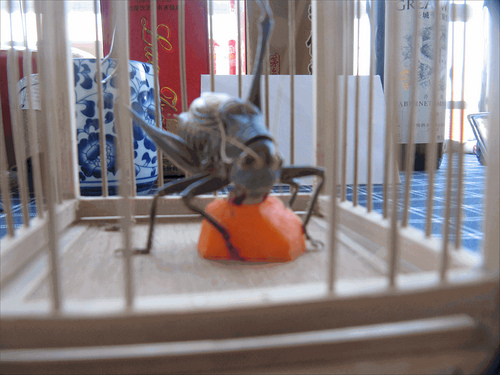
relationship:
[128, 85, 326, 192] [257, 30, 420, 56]
insect eating in cage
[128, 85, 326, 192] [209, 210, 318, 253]
insect eating carrot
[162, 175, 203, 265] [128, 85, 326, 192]
legs of insect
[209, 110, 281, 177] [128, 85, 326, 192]
antenna of insect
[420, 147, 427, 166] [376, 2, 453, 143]
wine bottle with white label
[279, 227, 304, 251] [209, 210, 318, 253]
edge of carrot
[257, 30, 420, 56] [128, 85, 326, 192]
cage holding insect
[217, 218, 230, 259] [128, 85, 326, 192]
hand of insect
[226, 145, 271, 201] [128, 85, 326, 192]
face of insect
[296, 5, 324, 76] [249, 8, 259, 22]
gold symbols on wall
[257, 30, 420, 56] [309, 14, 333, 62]
cage has white spindles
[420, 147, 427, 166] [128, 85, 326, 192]
wine bottle behind insect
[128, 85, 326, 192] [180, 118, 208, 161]
insect has wings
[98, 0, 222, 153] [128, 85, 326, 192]
box behind insect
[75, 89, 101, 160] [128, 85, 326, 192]
mug behind insect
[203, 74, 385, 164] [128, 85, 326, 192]
white board behind insect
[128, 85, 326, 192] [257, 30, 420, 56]
insect in cage